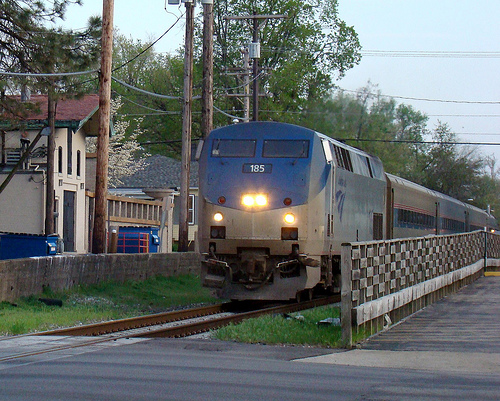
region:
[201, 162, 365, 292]
this is a train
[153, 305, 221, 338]
this is a railway line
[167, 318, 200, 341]
this is a metal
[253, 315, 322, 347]
this is a grass area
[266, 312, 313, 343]
the grass is green in color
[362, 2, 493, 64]
this is the sky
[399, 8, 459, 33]
the sky is blue in color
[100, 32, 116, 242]
this is a pole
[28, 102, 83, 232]
this is a building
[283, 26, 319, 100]
this is a tree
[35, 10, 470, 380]
A train is traveling through the city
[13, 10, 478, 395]
The train is carrying passengers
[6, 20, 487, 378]
The train is on railroad tracks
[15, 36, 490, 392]
The train is moving quickly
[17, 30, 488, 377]
The train is pulling many cars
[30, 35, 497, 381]
The train has its lights on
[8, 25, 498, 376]
The train is going to a station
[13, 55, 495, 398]
The train is passing a crossing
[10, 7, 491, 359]
The train is passing some house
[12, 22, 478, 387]
The train is close to some trees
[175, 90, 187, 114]
prt of a pole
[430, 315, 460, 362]
part of a floor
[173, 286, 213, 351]
part of a rail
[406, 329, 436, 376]
part of a floor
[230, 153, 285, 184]
white number on train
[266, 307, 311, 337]
green grass next to train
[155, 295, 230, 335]
track under the train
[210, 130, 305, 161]
window on the train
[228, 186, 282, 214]
lights on front of train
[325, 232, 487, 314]
fence next to train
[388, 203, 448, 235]
windows on side of train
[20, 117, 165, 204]
poles next to train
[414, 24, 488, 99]
wires above the train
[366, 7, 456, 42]
blue sky above the land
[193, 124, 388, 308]
a blue and silver train engine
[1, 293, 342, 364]
a set of train tracks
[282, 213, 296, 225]
a train engine front headlight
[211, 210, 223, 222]
a train engine front headlight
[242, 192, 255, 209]
a train engine front headlight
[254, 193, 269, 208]
a train engine front headlight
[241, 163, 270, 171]
a train identification number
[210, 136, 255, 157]
a train engine windshield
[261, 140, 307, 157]
a train engine windshield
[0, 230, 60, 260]
a blue trash dumpster